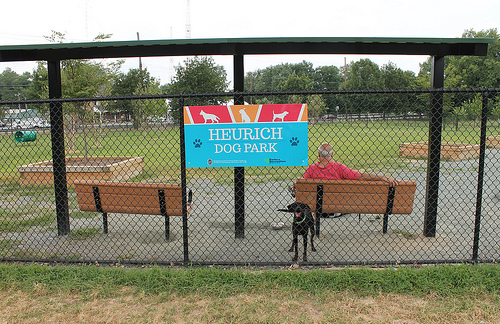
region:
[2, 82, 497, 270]
fence is black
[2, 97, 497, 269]
fence is made of metal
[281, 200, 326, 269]
medium sized black dog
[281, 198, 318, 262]
dog has it's tongue hanging out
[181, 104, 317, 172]
sign is blue, red, orange, white, and black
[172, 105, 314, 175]
sign is for a dog park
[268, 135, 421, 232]
man sitting on bench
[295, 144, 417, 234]
bench made of wood and metal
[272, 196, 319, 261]
dog is looking at camera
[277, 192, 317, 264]
dog is wearing a blue collar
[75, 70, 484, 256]
picture taken outdoors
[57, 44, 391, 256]
picture taken during the day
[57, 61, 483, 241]
picture is of a dog park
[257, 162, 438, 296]
a black dog is behind the fence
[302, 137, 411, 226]
a man is sitting on a bench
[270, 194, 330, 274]
the dog is looking at the camera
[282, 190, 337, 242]
the dog's tongue is out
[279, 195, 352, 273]
the dog is black in color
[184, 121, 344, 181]
the sign says Heurich Dog Park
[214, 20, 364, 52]
the sky is light gray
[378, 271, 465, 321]
part of some grass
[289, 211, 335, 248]
part of a meshed fence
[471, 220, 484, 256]
part of a metal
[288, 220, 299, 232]
chest of a dog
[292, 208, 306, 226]
part of a tongue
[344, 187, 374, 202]
part of a bench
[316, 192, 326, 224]
part of a metal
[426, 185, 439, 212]
part of a post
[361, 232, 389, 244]
part of a floor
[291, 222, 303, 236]
part of a neck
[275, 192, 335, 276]
the dog is black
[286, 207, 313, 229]
the dog is wearing a collar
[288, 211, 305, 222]
the dog's tongue is pink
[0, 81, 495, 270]
the dog is standing behind a fence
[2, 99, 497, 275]
the fence is black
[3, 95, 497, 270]
the fence is made of metal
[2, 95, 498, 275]
the fence is chain link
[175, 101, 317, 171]
the sign says heurich dog park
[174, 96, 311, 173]
the sign is blue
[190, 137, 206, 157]
the sign has paw prints on it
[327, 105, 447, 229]
this is a fence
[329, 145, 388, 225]
the fence is made with wire mess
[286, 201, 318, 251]
this is a dog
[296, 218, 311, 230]
the dog is black in color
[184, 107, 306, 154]
this is a notice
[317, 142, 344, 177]
this is a man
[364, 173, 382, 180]
the man is light skinned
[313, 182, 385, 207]
this is a bench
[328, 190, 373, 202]
the bench is made of wood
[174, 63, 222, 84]
this is a tree